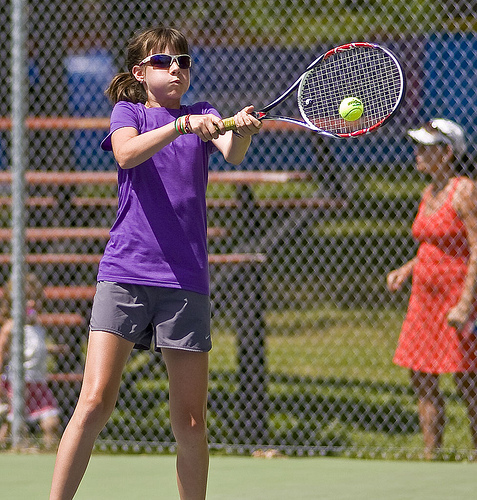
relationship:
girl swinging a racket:
[48, 24, 268, 499] [183, 36, 410, 166]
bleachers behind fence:
[0, 70, 351, 432] [4, 3, 472, 456]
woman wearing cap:
[385, 111, 477, 459] [405, 114, 466, 160]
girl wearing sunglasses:
[42, 33, 260, 493] [129, 51, 194, 70]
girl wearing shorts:
[42, 33, 260, 493] [77, 275, 220, 352]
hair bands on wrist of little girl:
[173, 110, 191, 137] [30, 8, 274, 497]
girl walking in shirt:
[48, 24, 268, 499] [1, 321, 50, 380]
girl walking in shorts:
[48, 24, 268, 499] [4, 380, 60, 422]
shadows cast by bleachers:
[117, 381, 420, 454] [6, 103, 352, 348]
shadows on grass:
[117, 381, 420, 454] [273, 314, 397, 442]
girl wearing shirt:
[42, 33, 260, 493] [101, 95, 216, 289]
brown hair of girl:
[108, 24, 190, 104] [42, 33, 260, 493]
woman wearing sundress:
[377, 103, 473, 460] [391, 177, 475, 377]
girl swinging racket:
[48, 24, 268, 499] [212, 42, 410, 142]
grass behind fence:
[339, 312, 368, 346] [35, 20, 475, 471]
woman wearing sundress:
[385, 111, 477, 459] [391, 175, 477, 378]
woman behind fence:
[385, 111, 477, 459] [4, 3, 472, 456]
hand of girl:
[229, 82, 299, 160] [44, 13, 404, 340]